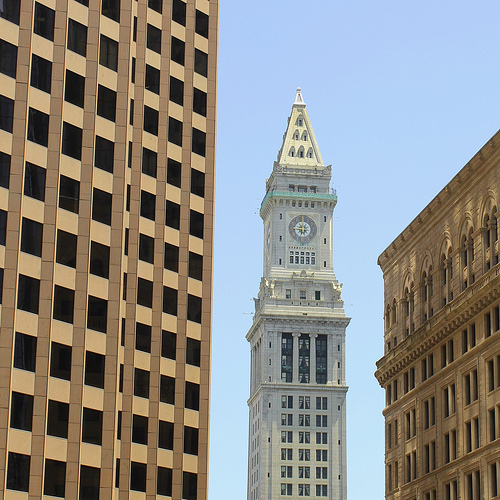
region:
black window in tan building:
[63, 66, 86, 111]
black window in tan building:
[72, 336, 116, 401]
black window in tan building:
[33, 330, 75, 387]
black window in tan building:
[43, 394, 73, 451]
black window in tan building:
[3, 388, 38, 443]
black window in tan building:
[123, 411, 158, 466]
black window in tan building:
[149, 411, 182, 455]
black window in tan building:
[186, 413, 208, 461]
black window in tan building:
[157, 278, 191, 340]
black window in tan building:
[414, 348, 481, 393]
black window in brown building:
[19, 53, 57, 97]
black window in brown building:
[6, 327, 48, 385]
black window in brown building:
[76, 346, 104, 388]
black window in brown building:
[396, 353, 423, 403]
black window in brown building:
[432, 425, 464, 457]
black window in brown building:
[185, 247, 202, 285]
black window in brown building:
[181, 420, 206, 465]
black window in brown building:
[139, 100, 163, 145]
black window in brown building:
[155, 110, 185, 155]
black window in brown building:
[184, 109, 211, 164]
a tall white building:
[250, 91, 365, 497]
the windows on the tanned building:
[27, 170, 117, 210]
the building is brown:
[380, 225, 492, 492]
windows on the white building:
[278, 393, 327, 412]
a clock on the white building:
[287, 219, 314, 241]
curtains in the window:
[296, 447, 311, 461]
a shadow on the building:
[402, 235, 449, 254]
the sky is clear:
[320, 88, 475, 156]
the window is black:
[42, 461, 67, 493]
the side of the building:
[247, 404, 262, 499]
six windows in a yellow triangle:
[278, 106, 320, 166]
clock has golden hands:
[285, 212, 318, 245]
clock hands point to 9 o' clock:
[286, 212, 308, 233]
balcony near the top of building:
[259, 187, 342, 207]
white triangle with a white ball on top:
[290, 82, 306, 106]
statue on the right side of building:
[328, 281, 343, 307]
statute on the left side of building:
[259, 277, 274, 302]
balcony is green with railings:
[270, 187, 335, 202]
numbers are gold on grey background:
[307, 216, 317, 244]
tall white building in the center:
[240, 82, 349, 498]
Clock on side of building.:
[286, 210, 318, 247]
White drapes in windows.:
[292, 338, 313, 383]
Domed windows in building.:
[409, 246, 439, 326]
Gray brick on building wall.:
[261, 407, 281, 446]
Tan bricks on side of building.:
[385, 265, 412, 292]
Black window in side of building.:
[47, 279, 78, 332]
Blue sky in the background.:
[357, 113, 417, 178]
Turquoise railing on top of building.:
[265, 184, 335, 205]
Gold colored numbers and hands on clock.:
[286, 213, 321, 248]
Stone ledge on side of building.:
[375, 257, 495, 392]